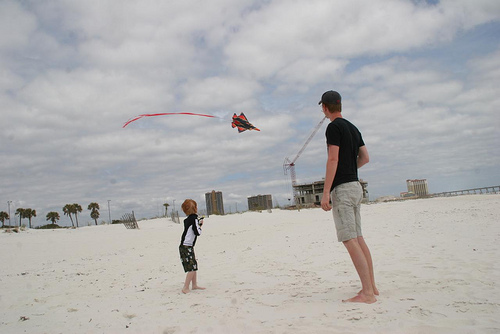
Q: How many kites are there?
A: One.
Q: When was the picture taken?
A: Daytime.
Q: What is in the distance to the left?
A: Palm trees.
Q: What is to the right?
A: Bridge.